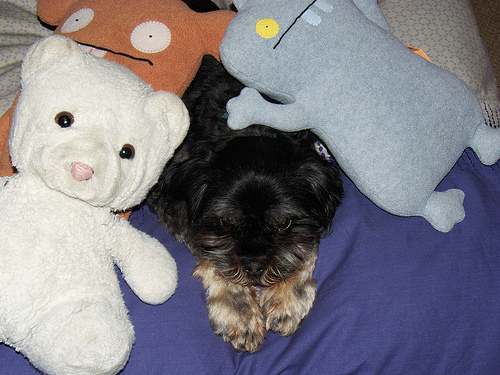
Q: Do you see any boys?
A: No, there are no boys.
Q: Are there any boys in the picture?
A: No, there are no boys.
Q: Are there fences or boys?
A: No, there are no boys or fences.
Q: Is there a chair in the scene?
A: No, there are no chairs.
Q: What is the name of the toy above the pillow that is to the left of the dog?
A: The toy is a stuffed animal.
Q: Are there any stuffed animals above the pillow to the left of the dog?
A: Yes, there is a stuffed animal above the pillow.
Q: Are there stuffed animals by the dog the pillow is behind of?
A: Yes, there is a stuffed animal by the dog.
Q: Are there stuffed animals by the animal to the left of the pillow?
A: Yes, there is a stuffed animal by the dog.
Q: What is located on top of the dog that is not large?
A: The stuffed animal is on top of the dog.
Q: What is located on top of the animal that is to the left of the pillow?
A: The stuffed animal is on top of the dog.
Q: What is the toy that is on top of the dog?
A: The toy is a stuffed animal.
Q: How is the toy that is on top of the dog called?
A: The toy is a stuffed animal.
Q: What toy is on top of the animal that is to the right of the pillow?
A: The toy is a stuffed animal.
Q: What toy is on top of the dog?
A: The toy is a stuffed animal.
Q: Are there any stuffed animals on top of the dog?
A: Yes, there is a stuffed animal on top of the dog.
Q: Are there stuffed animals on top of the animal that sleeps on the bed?
A: Yes, there is a stuffed animal on top of the dog.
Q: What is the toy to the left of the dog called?
A: The toy is a stuffed animal.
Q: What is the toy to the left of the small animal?
A: The toy is a stuffed animal.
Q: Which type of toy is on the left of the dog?
A: The toy is a stuffed animal.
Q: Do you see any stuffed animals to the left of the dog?
A: Yes, there is a stuffed animal to the left of the dog.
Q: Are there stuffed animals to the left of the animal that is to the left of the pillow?
A: Yes, there is a stuffed animal to the left of the dog.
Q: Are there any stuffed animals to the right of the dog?
A: No, the stuffed animal is to the left of the dog.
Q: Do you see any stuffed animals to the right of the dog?
A: No, the stuffed animal is to the left of the dog.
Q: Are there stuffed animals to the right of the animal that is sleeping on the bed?
A: No, the stuffed animal is to the left of the dog.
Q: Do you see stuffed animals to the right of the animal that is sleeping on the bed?
A: No, the stuffed animal is to the left of the dog.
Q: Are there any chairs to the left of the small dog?
A: No, there is a stuffed animal to the left of the dog.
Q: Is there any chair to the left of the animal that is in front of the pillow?
A: No, there is a stuffed animal to the left of the dog.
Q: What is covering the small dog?
A: The stuffed animal is covering the dog.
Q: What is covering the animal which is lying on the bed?
A: The stuffed animal is covering the dog.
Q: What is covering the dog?
A: The stuffed animal is covering the dog.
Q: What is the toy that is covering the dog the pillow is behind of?
A: The toy is a stuffed animal.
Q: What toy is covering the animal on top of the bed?
A: The toy is a stuffed animal.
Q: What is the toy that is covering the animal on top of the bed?
A: The toy is a stuffed animal.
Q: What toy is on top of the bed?
A: The toy is a stuffed animal.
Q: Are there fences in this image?
A: No, there are no fences.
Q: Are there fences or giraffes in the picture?
A: No, there are no fences or giraffes.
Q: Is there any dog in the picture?
A: Yes, there is a dog.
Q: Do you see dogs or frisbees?
A: Yes, there is a dog.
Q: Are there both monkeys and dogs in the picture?
A: No, there is a dog but no monkeys.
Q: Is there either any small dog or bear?
A: Yes, there is a small dog.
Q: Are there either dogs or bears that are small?
A: Yes, the dog is small.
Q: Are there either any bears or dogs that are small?
A: Yes, the dog is small.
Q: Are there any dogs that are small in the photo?
A: Yes, there is a small dog.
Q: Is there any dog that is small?
A: Yes, there is a dog that is small.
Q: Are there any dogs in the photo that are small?
A: Yes, there is a dog that is small.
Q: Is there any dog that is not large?
A: Yes, there is a small dog.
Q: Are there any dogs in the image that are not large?
A: Yes, there is a small dog.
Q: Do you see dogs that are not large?
A: Yes, there is a small dog.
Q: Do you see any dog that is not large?
A: Yes, there is a small dog.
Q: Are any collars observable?
A: No, there are no collars.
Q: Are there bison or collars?
A: No, there are no collars or bison.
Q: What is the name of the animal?
A: The animal is a dog.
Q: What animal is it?
A: The animal is a dog.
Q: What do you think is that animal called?
A: This is a dog.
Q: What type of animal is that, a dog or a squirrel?
A: This is a dog.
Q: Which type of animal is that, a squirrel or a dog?
A: This is a dog.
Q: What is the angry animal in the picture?
A: The animal is a dog.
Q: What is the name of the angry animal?
A: The animal is a dog.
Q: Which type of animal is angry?
A: The animal is a dog.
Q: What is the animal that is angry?
A: The animal is a dog.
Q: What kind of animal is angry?
A: The animal is a dog.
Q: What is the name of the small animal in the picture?
A: The animal is a dog.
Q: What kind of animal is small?
A: The animal is a dog.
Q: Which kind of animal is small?
A: The animal is a dog.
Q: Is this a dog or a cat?
A: This is a dog.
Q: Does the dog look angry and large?
A: No, the dog is angry but small.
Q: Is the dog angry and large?
A: No, the dog is angry but small.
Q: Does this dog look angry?
A: Yes, the dog is angry.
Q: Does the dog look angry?
A: Yes, the dog is angry.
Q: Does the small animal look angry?
A: Yes, the dog is angry.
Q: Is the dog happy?
A: No, the dog is angry.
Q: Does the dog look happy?
A: No, the dog is angry.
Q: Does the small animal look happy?
A: No, the dog is angry.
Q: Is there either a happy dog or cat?
A: No, there is a dog but it is angry.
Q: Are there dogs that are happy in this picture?
A: No, there is a dog but it is angry.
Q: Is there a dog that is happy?
A: No, there is a dog but it is angry.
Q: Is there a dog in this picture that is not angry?
A: No, there is a dog but it is angry.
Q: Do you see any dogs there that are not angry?
A: No, there is a dog but it is angry.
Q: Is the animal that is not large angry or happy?
A: The dog is angry.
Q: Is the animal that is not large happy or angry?
A: The dog is angry.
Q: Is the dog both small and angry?
A: Yes, the dog is small and angry.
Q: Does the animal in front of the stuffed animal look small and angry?
A: Yes, the dog is small and angry.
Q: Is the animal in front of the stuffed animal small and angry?
A: Yes, the dog is small and angry.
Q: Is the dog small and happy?
A: No, the dog is small but angry.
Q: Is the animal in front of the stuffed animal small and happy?
A: No, the dog is small but angry.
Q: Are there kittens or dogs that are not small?
A: No, there is a dog but it is small.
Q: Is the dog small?
A: Yes, the dog is small.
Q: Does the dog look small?
A: Yes, the dog is small.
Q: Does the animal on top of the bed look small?
A: Yes, the dog is small.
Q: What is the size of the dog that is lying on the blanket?
A: The dog is small.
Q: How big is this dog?
A: The dog is small.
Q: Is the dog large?
A: No, the dog is small.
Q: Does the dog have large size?
A: No, the dog is small.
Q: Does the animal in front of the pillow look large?
A: No, the dog is small.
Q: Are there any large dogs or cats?
A: No, there is a dog but it is small.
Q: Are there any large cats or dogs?
A: No, there is a dog but it is small.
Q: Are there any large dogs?
A: No, there is a dog but it is small.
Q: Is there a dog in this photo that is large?
A: No, there is a dog but it is small.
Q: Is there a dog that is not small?
A: No, there is a dog but it is small.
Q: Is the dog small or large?
A: The dog is small.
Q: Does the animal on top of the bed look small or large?
A: The dog is small.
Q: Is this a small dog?
A: Yes, this is a small dog.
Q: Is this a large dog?
A: No, this is a small dog.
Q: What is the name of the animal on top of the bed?
A: The animal is a dog.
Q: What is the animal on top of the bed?
A: The animal is a dog.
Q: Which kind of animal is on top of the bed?
A: The animal is a dog.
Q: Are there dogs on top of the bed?
A: Yes, there is a dog on top of the bed.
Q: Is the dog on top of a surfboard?
A: No, the dog is on top of the bed.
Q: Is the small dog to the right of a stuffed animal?
A: Yes, the dog is to the right of a stuffed animal.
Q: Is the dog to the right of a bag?
A: No, the dog is to the right of a stuffed animal.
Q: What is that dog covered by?
A: The dog is covered by the stuffed animal.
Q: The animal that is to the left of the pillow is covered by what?
A: The dog is covered by the stuffed animal.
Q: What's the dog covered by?
A: The dog is covered by the stuffed animal.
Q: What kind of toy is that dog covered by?
A: The dog is covered by the stuffed animal.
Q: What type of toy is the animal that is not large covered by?
A: The dog is covered by the stuffed animal.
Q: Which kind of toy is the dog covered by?
A: The dog is covered by the stuffed animal.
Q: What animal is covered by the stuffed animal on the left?
A: The dog is covered by the stuffed animal.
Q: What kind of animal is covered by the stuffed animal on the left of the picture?
A: The animal is a dog.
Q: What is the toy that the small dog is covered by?
A: The toy is a stuffed animal.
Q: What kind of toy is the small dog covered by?
A: The dog is covered by the stuffed animal.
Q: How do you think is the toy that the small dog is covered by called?
A: The toy is a stuffed animal.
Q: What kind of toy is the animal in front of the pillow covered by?
A: The dog is covered by the stuffed animal.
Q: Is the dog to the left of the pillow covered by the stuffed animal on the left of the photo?
A: Yes, the dog is covered by the stuffed animal.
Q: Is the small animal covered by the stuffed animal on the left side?
A: Yes, the dog is covered by the stuffed animal.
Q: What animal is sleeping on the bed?
A: The animal is a dog.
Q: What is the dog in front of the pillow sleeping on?
A: The dog is sleeping on the bed.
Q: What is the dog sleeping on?
A: The dog is sleeping on the bed.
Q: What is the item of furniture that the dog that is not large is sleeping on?
A: The piece of furniture is a bed.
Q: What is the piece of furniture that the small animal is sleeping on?
A: The piece of furniture is a bed.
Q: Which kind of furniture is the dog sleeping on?
A: The dog is sleeping on the bed.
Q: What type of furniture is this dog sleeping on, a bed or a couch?
A: The dog is sleeping on a bed.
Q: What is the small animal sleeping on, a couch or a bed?
A: The dog is sleeping on a bed.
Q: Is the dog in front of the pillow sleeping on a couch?
A: No, the dog is sleeping on the bed.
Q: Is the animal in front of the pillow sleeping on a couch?
A: No, the dog is sleeping on the bed.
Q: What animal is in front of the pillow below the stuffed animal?
A: The dog is in front of the pillow.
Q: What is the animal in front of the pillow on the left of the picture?
A: The animal is a dog.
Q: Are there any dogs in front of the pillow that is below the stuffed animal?
A: Yes, there is a dog in front of the pillow.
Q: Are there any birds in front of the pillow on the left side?
A: No, there is a dog in front of the pillow.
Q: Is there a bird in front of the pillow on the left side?
A: No, there is a dog in front of the pillow.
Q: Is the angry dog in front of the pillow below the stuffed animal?
A: Yes, the dog is in front of the pillow.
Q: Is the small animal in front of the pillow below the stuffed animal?
A: Yes, the dog is in front of the pillow.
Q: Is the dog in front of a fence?
A: No, the dog is in front of the pillow.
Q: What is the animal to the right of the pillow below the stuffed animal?
A: The animal is a dog.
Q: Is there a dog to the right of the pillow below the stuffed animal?
A: Yes, there is a dog to the right of the pillow.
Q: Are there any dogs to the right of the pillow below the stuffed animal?
A: Yes, there is a dog to the right of the pillow.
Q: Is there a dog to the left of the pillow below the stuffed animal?
A: No, the dog is to the right of the pillow.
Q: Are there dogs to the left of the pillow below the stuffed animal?
A: No, the dog is to the right of the pillow.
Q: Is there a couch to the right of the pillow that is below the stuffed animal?
A: No, there is a dog to the right of the pillow.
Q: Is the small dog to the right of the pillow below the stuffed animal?
A: Yes, the dog is to the right of the pillow.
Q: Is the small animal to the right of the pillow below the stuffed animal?
A: Yes, the dog is to the right of the pillow.